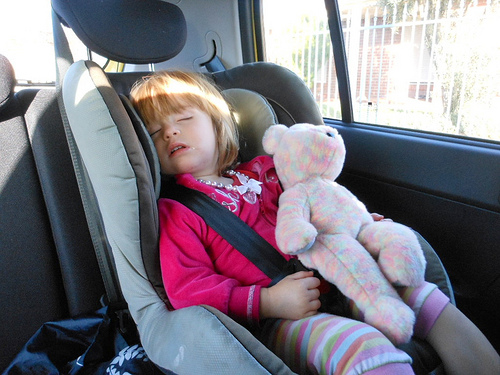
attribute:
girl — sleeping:
[92, 54, 377, 358]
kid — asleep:
[127, 65, 496, 374]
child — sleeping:
[126, 69, 494, 372]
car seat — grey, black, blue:
[52, 47, 462, 374]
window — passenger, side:
[250, 5, 497, 131]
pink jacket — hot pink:
[155, 160, 294, 317]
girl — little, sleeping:
[129, 72, 265, 307]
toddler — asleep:
[122, 67, 499, 374]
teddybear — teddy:
[254, 115, 451, 354]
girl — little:
[130, 72, 498, 371]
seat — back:
[18, 12, 318, 372]